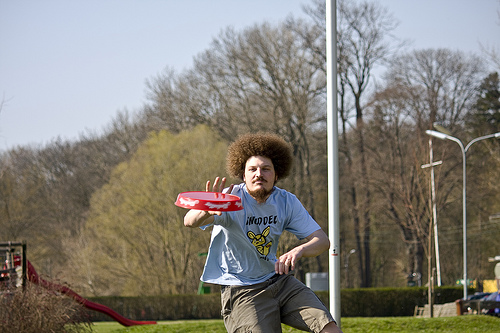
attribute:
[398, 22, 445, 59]
clouds — white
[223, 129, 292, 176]
afro — brownish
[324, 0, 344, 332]
pole — silver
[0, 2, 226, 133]
sky — blue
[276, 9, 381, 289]
tree — tall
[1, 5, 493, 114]
sky — blue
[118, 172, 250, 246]
frisbee — red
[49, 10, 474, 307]
trees — leafless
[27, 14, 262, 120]
sky — blue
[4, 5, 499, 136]
clouds — white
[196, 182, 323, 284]
tshirt — blue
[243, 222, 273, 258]
cartoon character — yellow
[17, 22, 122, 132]
sky — blue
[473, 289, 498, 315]
car — distant, parked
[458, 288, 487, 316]
car — distant, parked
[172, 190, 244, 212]
frisbee — red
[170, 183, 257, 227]
frisbee — red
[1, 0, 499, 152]
sky — blue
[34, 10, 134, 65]
cloud — white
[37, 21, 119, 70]
sky — blue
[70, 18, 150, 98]
clouds — white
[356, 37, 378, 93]
branches — leafless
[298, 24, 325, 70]
branches — leafless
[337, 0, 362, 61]
branches — leafless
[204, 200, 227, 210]
shape — white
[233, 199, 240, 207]
shape — white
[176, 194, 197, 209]
shape — white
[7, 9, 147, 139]
sky — blue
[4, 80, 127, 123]
clouds — white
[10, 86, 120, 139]
clouds — white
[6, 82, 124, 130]
clouds — white